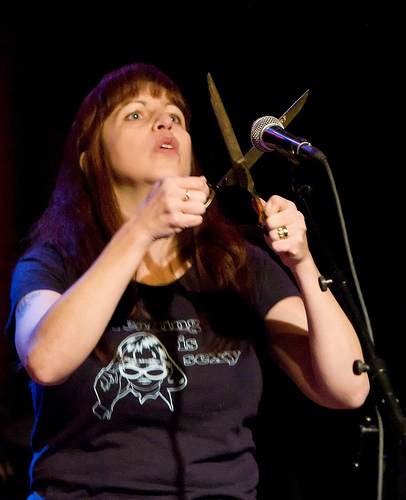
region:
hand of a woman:
[139, 174, 212, 239]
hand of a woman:
[247, 192, 311, 258]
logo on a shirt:
[85, 323, 191, 429]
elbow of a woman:
[26, 333, 75, 400]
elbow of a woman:
[334, 377, 377, 414]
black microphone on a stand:
[244, 102, 318, 168]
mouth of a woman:
[154, 135, 182, 154]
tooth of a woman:
[160, 140, 168, 149]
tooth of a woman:
[164, 142, 172, 149]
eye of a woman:
[121, 106, 145, 123]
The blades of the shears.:
[199, 72, 308, 174]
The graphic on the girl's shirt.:
[106, 312, 246, 418]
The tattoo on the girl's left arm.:
[9, 296, 41, 320]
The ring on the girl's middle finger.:
[183, 186, 188, 199]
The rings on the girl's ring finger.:
[278, 225, 288, 237]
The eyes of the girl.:
[121, 104, 191, 124]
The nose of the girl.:
[154, 115, 173, 129]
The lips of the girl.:
[152, 137, 180, 156]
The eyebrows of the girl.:
[114, 93, 177, 112]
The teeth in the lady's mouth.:
[158, 143, 171, 148]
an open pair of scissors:
[201, 70, 310, 228]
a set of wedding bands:
[277, 225, 288, 240]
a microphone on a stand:
[248, 115, 404, 499]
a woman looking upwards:
[2, 60, 371, 499]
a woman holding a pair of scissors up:
[3, 59, 370, 499]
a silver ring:
[182, 186, 190, 202]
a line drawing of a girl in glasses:
[89, 329, 188, 420]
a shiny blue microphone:
[248, 113, 324, 168]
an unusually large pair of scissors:
[201, 69, 311, 233]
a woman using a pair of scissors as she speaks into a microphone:
[0, 59, 404, 499]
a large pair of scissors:
[196, 69, 317, 227]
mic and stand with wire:
[253, 101, 404, 386]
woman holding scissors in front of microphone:
[71, 60, 393, 285]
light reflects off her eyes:
[75, 67, 207, 202]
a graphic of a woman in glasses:
[91, 325, 218, 415]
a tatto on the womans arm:
[10, 279, 44, 328]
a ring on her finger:
[268, 216, 307, 256]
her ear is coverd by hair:
[71, 147, 101, 185]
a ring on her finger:
[174, 177, 202, 212]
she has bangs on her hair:
[95, 71, 201, 119]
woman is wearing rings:
[245, 191, 317, 282]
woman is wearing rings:
[259, 198, 297, 253]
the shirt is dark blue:
[27, 218, 288, 499]